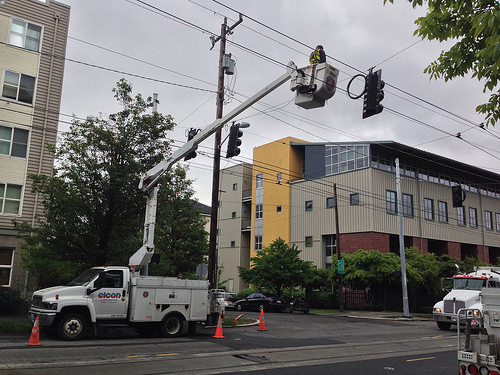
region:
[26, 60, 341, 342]
White cherrypicker truck with boom raised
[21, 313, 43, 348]
Orange and white traffic cone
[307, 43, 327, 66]
Man in cherrypicker bucket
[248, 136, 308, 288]
Tall yellow building with addition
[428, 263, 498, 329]
Large white tanker truck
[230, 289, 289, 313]
Small black car parked at curb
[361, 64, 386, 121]
Traffic light hanging above street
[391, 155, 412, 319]
Tall white post for power lines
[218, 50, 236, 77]
Pair of electrical transformers on post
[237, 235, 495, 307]
Green trees along sidewalk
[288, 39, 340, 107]
Man in bucket is working on the power lines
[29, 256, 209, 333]
white utlity truck parked by the curve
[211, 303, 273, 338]
one of the three orange cones is bent over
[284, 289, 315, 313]
motorcycle parked near the sidewalk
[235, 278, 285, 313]
dark car parked under the tree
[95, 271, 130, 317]
driver door has company logo on it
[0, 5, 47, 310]
this building is five stories tall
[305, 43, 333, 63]
man wearing safety harness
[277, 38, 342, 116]
this man is working very high off the ground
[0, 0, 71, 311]
THATS A PARTIAL BUILDING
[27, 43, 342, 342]
A WHITE UTILITY TRUCK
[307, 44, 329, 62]
A MAN STANDING INSIDE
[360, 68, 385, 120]
THIS IS A TRAFFIC LIGHT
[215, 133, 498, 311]
THIS IS A BUILDING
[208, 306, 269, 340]
THESE ARE ORANGE CONES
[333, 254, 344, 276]
THATS A GREEN SIGN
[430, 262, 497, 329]
THIS IS A WHITE TRUCK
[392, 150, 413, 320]
THATS A SILVER POLE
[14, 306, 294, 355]
the cones at the street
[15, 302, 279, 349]
the cones at the street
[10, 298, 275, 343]
the cones at the street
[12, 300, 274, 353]
the cones at the street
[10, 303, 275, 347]
the cones at the street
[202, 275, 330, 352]
black car is parked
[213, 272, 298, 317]
black car is parked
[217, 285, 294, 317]
black car is parked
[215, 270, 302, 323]
black car is parked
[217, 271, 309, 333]
black car is parked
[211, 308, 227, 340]
The cone is orange.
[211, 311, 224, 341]
The cone is on the ground.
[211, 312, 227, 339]
The cone has a point.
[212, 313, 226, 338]
The cone has stripes.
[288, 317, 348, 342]
The pavement is black.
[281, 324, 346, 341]
The pavement is smooth.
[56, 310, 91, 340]
The front tire is black.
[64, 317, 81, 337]
The hub cap is white.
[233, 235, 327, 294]
The tree in the background is green.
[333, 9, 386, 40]
The sky is gray.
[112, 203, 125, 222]
green leaves on the tree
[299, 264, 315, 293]
green leaves on the tree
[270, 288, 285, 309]
green leaves on the tree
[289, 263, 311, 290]
green leaves on the tree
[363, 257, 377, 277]
green leaves on the tree